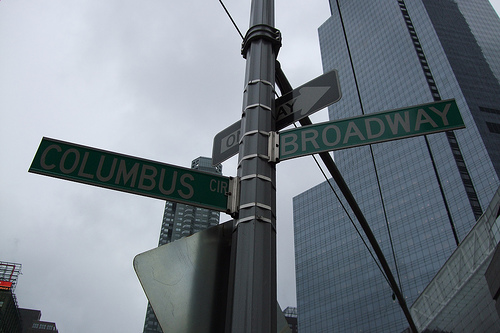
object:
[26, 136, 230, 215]
street sign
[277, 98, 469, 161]
street sign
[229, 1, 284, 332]
pole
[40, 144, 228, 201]
writing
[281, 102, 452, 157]
writing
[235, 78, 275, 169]
sign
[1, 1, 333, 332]
sky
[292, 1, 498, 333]
building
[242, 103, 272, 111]
ring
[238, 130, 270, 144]
ring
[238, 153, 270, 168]
ring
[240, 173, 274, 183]
ring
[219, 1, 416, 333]
wire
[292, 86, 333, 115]
arrow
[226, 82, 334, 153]
writing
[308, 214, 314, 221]
window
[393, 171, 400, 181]
window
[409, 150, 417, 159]
window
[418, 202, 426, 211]
window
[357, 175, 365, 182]
window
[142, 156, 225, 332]
building